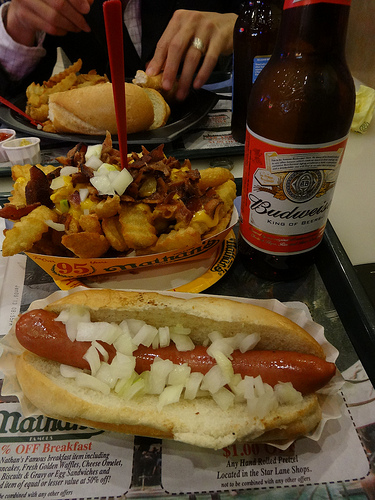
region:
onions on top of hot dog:
[62, 309, 298, 403]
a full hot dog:
[17, 286, 325, 445]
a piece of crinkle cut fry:
[1, 208, 50, 251]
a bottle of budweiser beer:
[241, 4, 357, 282]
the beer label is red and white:
[240, 121, 351, 253]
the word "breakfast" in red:
[39, 442, 92, 451]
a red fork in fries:
[100, 0, 132, 177]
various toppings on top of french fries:
[30, 141, 205, 230]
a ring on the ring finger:
[187, 35, 207, 51]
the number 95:
[53, 261, 92, 277]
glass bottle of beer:
[245, 3, 351, 285]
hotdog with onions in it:
[16, 288, 347, 461]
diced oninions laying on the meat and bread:
[48, 310, 321, 438]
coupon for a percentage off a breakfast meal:
[2, 396, 152, 498]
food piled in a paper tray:
[3, 154, 245, 272]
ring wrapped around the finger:
[189, 33, 206, 50]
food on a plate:
[9, 75, 215, 144]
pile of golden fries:
[20, 62, 131, 126]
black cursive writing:
[250, 195, 338, 226]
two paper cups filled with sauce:
[1, 123, 46, 166]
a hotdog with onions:
[9, 293, 336, 454]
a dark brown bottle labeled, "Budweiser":
[242, 0, 357, 287]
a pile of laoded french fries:
[8, 159, 238, 254]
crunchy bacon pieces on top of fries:
[5, 137, 219, 224]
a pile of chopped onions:
[56, 307, 305, 413]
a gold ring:
[189, 37, 208, 53]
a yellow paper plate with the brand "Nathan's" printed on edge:
[38, 229, 238, 293]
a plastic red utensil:
[100, 3, 126, 177]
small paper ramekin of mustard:
[0, 134, 39, 161]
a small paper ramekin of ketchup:
[1, 127, 14, 164]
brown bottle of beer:
[252, 27, 335, 248]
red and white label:
[244, 128, 327, 234]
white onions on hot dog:
[36, 306, 265, 439]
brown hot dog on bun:
[17, 309, 321, 391]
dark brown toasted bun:
[36, 289, 336, 427]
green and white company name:
[0, 401, 102, 459]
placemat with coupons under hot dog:
[1, 394, 358, 471]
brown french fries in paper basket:
[7, 171, 229, 243]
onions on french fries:
[44, 150, 176, 220]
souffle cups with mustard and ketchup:
[0, 127, 47, 163]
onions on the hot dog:
[68, 310, 262, 413]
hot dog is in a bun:
[17, 278, 339, 447]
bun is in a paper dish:
[0, 281, 343, 451]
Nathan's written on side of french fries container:
[113, 236, 231, 283]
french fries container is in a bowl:
[143, 251, 220, 293]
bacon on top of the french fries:
[25, 165, 229, 228]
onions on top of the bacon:
[80, 140, 129, 201]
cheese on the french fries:
[188, 195, 223, 231]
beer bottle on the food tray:
[246, 0, 341, 287]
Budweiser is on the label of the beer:
[241, 184, 364, 234]